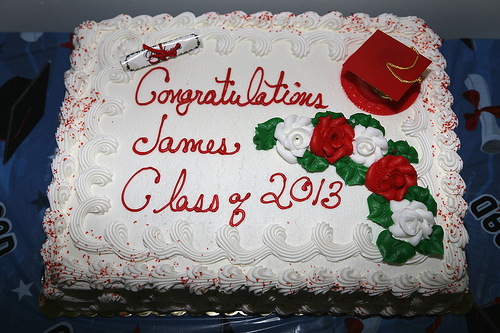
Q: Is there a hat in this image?
A: Yes, there is a hat.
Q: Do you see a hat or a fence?
A: Yes, there is a hat.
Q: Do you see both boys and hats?
A: No, there is a hat but no boys.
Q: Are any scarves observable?
A: No, there are no scarves.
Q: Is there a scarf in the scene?
A: No, there are no scarves.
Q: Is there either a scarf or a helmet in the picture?
A: No, there are no scarves or helmets.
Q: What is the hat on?
A: The hat is on the cake.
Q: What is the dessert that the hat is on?
A: The dessert is a cake.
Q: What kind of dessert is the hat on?
A: The hat is on the cake.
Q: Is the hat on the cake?
A: Yes, the hat is on the cake.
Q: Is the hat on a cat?
A: No, the hat is on the cake.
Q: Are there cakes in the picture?
A: Yes, there is a cake.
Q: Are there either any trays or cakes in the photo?
A: Yes, there is a cake.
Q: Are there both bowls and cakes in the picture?
A: No, there is a cake but no bowls.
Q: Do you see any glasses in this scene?
A: No, there are no glasses.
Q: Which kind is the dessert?
A: The dessert is a cake.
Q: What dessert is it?
A: The dessert is a cake.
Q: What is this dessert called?
A: This is a cake.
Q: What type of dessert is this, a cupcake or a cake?
A: This is a cake.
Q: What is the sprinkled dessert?
A: The dessert is a cake.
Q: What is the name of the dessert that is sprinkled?
A: The dessert is a cake.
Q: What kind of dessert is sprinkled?
A: The dessert is a cake.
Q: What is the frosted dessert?
A: The dessert is a cake.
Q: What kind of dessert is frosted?
A: The dessert is a cake.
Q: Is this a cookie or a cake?
A: This is a cake.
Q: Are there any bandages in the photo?
A: No, there are no bandages.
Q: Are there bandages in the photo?
A: No, there are no bandages.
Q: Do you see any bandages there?
A: No, there are no bandages.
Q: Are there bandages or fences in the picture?
A: No, there are no bandages or fences.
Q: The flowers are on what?
A: The flowers are on the cake.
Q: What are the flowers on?
A: The flowers are on the cake.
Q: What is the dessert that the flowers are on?
A: The dessert is a cake.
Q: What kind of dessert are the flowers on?
A: The flowers are on the cake.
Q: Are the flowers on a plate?
A: No, the flowers are on the cake.